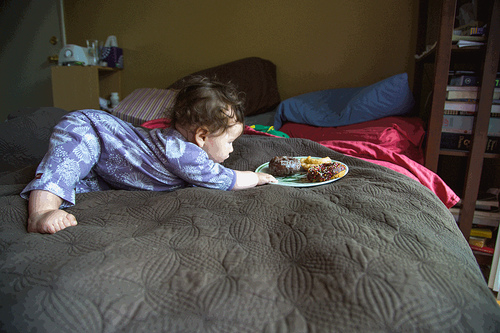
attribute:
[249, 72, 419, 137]
pillow — blue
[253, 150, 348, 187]
plate — round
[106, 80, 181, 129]
pillow — striped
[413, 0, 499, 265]
bookshelf — book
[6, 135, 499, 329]
bedspread — grey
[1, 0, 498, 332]
picture — indoor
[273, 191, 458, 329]
blanket — grey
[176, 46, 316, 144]
pillow — brown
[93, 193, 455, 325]
blanket — grey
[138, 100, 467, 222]
sheet — pink